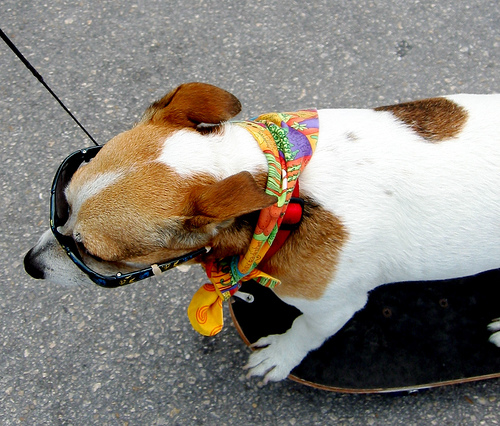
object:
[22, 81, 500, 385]
dog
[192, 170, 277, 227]
ear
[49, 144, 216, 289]
sunglasses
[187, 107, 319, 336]
bandana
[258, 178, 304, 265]
collar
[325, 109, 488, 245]
fur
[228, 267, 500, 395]
skateboard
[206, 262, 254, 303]
knot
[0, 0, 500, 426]
surface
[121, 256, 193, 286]
design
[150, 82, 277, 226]
ears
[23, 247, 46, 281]
nose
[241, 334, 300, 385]
paws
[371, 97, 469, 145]
spots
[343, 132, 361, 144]
spot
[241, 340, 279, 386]
nails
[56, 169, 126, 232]
stripe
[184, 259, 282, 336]
scarf